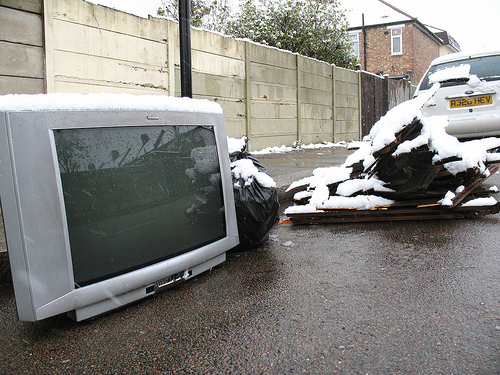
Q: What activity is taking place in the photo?
A: Littering.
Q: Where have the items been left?
A: In the street.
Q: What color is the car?
A: White.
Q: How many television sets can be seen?
A: One.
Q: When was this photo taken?
A: Daytime.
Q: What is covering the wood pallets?
A: Snow.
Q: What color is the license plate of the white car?
A: Yellow.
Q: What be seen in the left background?
A: A wall.